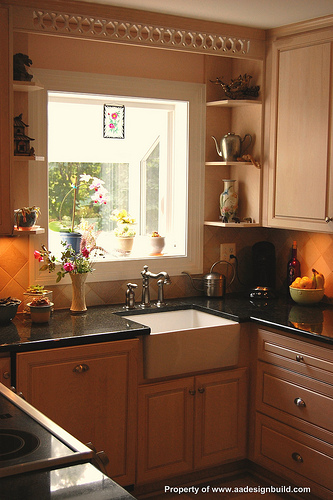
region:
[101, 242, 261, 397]
Farm style kitchen sink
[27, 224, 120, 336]
Flowers in a vase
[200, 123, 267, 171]
Teapot on a shelf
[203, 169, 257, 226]
Vase on a shelf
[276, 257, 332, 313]
Bowl of fruit on a counter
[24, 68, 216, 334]
Large window in the kitchen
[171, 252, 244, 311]
Watering can on the counter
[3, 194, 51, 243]
Wilting plant on the shelf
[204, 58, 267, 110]
Sculpture on a shelf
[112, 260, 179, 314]
Faucet with seperate handles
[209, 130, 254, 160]
metal teapot sitting on shelf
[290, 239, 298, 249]
cork in bottle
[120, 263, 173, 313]
metal faucet on kitchen sink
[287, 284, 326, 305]
white bowl sitting on counter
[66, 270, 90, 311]
white vase sitting on counter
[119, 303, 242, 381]
white apron sink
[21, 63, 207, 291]
white wood framed window above sink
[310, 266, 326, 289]
bananas sitting in white bowl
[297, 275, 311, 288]
orange sitting in white bowl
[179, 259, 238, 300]
metal water jug sitting on counter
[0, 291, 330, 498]
Black marble kitchen counter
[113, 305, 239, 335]
Sink on the counter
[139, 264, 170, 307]
Faucet over the sink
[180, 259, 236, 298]
Kettle on the counter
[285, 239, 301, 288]
A bottle of wine on the counter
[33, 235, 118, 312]
Fake flower on the counter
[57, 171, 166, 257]
Pot plants on the window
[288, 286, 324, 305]
Bowl on the counter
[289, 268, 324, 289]
Fruits in the bowl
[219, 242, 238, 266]
Plug in on the wall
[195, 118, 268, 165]
silver teapot on shelf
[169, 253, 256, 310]
silver teapot on counter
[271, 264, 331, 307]
bowl of fruit on table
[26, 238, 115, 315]
vase of flowers on table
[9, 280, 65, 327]
ornaments on table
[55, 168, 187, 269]
flowers on window sill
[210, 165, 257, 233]
vase on shelf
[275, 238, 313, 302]
bottle of wine on counter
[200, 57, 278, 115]
ornament on shelf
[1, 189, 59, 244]
pot plant on shelf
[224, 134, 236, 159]
A metallic pot on the shelf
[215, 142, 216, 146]
The spout of the pot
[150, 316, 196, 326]
The inside of a sink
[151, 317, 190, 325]
A white sink surface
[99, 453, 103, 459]
The knob of a stove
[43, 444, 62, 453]
Metallic surface of the stove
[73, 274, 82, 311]
A flower vase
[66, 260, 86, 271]
Flowers in a vase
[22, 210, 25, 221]
A withered plant